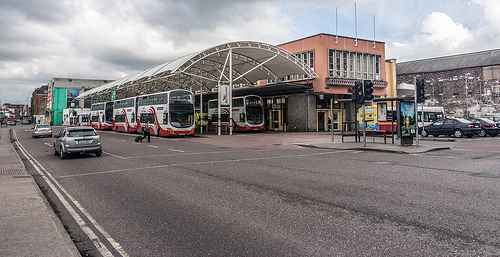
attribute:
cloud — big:
[100, 30, 136, 56]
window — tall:
[329, 50, 335, 79]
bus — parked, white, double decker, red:
[138, 87, 197, 136]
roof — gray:
[73, 44, 316, 92]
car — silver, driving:
[54, 128, 104, 162]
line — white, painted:
[40, 169, 93, 227]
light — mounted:
[354, 82, 365, 101]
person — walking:
[132, 119, 154, 143]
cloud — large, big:
[24, 12, 109, 44]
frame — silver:
[221, 49, 237, 83]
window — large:
[247, 96, 263, 123]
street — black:
[310, 152, 409, 180]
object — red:
[377, 121, 398, 133]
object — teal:
[53, 91, 67, 125]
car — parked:
[419, 115, 477, 137]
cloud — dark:
[144, 5, 215, 30]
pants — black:
[142, 131, 153, 144]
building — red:
[35, 95, 44, 110]